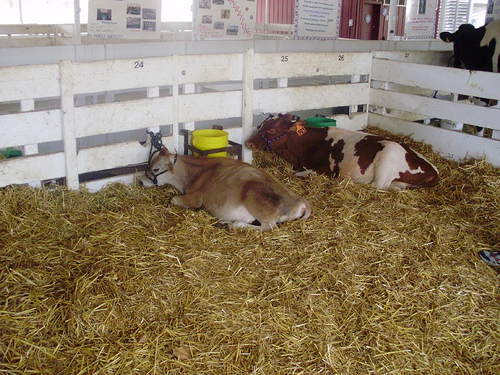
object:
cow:
[139, 144, 312, 233]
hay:
[1, 123, 499, 375]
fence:
[1, 50, 500, 194]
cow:
[245, 112, 440, 190]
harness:
[143, 130, 178, 187]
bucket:
[191, 128, 228, 158]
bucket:
[305, 116, 336, 126]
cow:
[439, 20, 499, 132]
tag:
[295, 123, 307, 137]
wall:
[256, 0, 442, 40]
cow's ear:
[290, 121, 305, 133]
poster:
[88, 0, 161, 40]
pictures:
[193, 0, 258, 41]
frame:
[178, 125, 242, 163]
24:
[133, 60, 145, 69]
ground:
[0, 205, 499, 373]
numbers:
[279, 54, 290, 63]